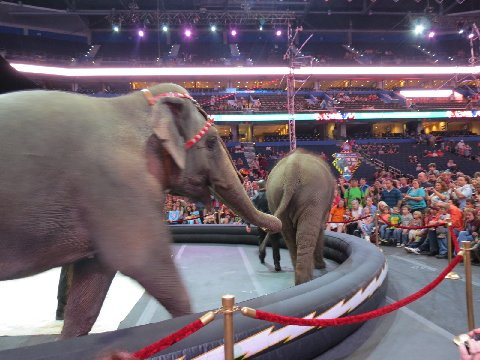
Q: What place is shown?
A: It is a stadium.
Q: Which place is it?
A: It is a stadium.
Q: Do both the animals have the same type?
A: Yes, all the animals are elephants.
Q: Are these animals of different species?
A: No, all the animals are elephants.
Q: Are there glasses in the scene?
A: No, there are no glasses.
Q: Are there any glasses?
A: No, there are no glasses.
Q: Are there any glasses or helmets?
A: No, there are no glasses or helmets.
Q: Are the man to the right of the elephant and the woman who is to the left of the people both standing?
A: Yes, both the man and the woman are standing.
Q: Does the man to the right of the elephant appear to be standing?
A: Yes, the man is standing.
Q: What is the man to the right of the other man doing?
A: The man is standing.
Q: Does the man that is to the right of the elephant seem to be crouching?
A: No, the man is standing.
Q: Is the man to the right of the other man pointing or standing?
A: The man is standing.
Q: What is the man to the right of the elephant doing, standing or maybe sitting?
A: The man is standing.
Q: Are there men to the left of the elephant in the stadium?
A: No, the man is to the right of the elephant.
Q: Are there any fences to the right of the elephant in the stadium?
A: No, there is a man to the right of the elephant.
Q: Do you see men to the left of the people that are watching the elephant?
A: Yes, there is a man to the left of the people.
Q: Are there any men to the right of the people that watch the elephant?
A: No, the man is to the left of the people.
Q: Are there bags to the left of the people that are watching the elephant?
A: No, there is a man to the left of the people.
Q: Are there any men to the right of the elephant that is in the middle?
A: Yes, there is a man to the right of the elephant.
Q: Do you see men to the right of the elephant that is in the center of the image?
A: Yes, there is a man to the right of the elephant.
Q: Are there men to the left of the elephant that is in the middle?
A: No, the man is to the right of the elephant.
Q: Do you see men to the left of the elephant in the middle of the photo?
A: No, the man is to the right of the elephant.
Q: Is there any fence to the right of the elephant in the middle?
A: No, there is a man to the right of the elephant.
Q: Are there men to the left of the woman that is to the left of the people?
A: Yes, there is a man to the left of the woman.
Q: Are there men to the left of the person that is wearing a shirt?
A: Yes, there is a man to the left of the woman.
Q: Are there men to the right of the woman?
A: No, the man is to the left of the woman.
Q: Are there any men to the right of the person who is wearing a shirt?
A: No, the man is to the left of the woman.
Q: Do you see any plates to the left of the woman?
A: No, there is a man to the left of the woman.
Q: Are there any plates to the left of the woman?
A: No, there is a man to the left of the woman.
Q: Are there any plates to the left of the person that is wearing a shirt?
A: No, there is a man to the left of the woman.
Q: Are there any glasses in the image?
A: No, there are no glasses.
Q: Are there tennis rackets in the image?
A: No, there are no tennis rackets.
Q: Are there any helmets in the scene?
A: No, there are no helmets.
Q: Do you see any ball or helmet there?
A: No, there are no helmets or balls.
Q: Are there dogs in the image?
A: No, there are no dogs.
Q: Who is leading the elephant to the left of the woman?
A: The man is leading the elephant.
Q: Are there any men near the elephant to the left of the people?
A: Yes, there is a man near the elephant.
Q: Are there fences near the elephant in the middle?
A: No, there is a man near the elephant.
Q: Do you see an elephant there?
A: Yes, there is an elephant.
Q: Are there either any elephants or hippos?
A: Yes, there is an elephant.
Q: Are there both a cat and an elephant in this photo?
A: No, there is an elephant but no cats.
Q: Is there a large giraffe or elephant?
A: Yes, there is a large elephant.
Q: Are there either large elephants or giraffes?
A: Yes, there is a large elephant.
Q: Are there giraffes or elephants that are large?
A: Yes, the elephant is large.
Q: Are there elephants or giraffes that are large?
A: Yes, the elephant is large.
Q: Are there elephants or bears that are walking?
A: Yes, the elephant is walking.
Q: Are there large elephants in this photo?
A: Yes, there is a large elephant.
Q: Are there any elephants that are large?
A: Yes, there is an elephant that is large.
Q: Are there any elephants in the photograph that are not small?
A: Yes, there is a large elephant.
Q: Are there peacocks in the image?
A: No, there are no peacocks.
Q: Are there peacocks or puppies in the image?
A: No, there are no peacocks or puppies.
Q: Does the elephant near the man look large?
A: Yes, the elephant is large.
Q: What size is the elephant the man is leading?
A: The elephant is large.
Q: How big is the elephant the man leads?
A: The elephant is large.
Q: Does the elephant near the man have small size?
A: No, the elephant is large.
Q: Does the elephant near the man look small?
A: No, the elephant is large.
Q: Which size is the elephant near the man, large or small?
A: The elephant is large.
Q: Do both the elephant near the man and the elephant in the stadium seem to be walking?
A: Yes, both the elephant and the elephant are walking.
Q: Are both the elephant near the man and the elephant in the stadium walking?
A: Yes, both the elephant and the elephant are walking.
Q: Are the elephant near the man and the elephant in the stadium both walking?
A: Yes, both the elephant and the elephant are walking.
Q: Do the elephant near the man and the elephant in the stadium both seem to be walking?
A: Yes, both the elephant and the elephant are walking.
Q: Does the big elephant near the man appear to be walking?
A: Yes, the elephant is walking.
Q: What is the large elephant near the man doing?
A: The elephant is walking.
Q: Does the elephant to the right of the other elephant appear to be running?
A: No, the elephant is walking.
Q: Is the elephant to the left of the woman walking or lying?
A: The elephant is walking.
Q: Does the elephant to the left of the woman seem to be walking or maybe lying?
A: The elephant is walking.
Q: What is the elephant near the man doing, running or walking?
A: The elephant is walking.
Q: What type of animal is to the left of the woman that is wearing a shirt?
A: The animal is an elephant.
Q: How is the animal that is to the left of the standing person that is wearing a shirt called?
A: The animal is an elephant.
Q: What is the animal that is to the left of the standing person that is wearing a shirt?
A: The animal is an elephant.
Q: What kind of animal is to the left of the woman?
A: The animal is an elephant.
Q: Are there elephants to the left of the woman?
A: Yes, there is an elephant to the left of the woman.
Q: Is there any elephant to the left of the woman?
A: Yes, there is an elephant to the left of the woman.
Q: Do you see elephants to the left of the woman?
A: Yes, there is an elephant to the left of the woman.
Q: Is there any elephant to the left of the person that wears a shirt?
A: Yes, there is an elephant to the left of the woman.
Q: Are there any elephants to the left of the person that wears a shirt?
A: Yes, there is an elephant to the left of the woman.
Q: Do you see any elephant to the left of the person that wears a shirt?
A: Yes, there is an elephant to the left of the woman.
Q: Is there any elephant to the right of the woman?
A: No, the elephant is to the left of the woman.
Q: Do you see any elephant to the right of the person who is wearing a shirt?
A: No, the elephant is to the left of the woman.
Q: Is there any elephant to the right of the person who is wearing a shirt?
A: No, the elephant is to the left of the woman.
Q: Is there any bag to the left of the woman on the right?
A: No, there is an elephant to the left of the woman.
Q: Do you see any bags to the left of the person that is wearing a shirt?
A: No, there is an elephant to the left of the woman.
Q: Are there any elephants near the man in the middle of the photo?
A: Yes, there is an elephant near the man.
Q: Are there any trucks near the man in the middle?
A: No, there is an elephant near the man.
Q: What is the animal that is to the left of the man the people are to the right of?
A: The animal is an elephant.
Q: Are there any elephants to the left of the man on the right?
A: Yes, there is an elephant to the left of the man.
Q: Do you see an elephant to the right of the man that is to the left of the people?
A: No, the elephant is to the left of the man.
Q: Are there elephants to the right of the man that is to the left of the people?
A: No, the elephant is to the left of the man.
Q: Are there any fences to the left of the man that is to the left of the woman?
A: No, there is an elephant to the left of the man.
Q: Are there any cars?
A: No, there are no cars.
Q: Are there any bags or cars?
A: No, there are no cars or bags.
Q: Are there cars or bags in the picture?
A: No, there are no cars or bags.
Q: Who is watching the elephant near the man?
A: The people are watching the elephant.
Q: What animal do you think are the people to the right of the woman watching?
A: The people are watching the elephant.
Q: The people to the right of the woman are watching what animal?
A: The people are watching the elephant.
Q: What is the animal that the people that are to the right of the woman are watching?
A: The animal is an elephant.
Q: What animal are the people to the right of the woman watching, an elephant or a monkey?
A: The people are watching an elephant.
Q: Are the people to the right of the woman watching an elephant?
A: Yes, the people are watching an elephant.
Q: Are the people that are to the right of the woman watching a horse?
A: No, the people are watching an elephant.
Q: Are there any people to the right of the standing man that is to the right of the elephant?
A: Yes, there are people to the right of the man.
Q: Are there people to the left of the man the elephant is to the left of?
A: No, the people are to the right of the man.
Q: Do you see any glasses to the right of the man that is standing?
A: No, there are people to the right of the man.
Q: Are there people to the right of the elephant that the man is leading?
A: Yes, there are people to the right of the elephant.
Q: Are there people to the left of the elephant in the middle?
A: No, the people are to the right of the elephant.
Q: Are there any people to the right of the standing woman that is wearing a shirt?
A: Yes, there are people to the right of the woman.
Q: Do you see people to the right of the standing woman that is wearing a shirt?
A: Yes, there are people to the right of the woman.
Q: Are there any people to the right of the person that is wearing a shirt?
A: Yes, there are people to the right of the woman.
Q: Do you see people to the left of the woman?
A: No, the people are to the right of the woman.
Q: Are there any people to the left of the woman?
A: No, the people are to the right of the woman.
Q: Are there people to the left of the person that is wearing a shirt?
A: No, the people are to the right of the woman.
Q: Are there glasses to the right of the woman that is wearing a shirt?
A: No, there are people to the right of the woman.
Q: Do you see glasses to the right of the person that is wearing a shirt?
A: No, there are people to the right of the woman.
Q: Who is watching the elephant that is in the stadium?
A: The people are watching the elephant.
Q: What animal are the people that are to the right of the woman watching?
A: The people are watching the elephant.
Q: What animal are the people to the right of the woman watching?
A: The people are watching the elephant.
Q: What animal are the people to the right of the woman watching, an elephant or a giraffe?
A: The people are watching an elephant.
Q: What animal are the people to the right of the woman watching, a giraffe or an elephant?
A: The people are watching an elephant.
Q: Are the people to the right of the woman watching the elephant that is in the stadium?
A: Yes, the people are watching the elephant.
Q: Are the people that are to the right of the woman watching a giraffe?
A: No, the people are watching the elephant.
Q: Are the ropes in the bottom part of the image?
A: Yes, the ropes are in the bottom of the image.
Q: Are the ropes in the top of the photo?
A: No, the ropes are in the bottom of the image.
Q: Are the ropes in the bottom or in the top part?
A: The ropes are in the bottom of the image.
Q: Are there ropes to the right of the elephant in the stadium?
A: Yes, there are ropes to the right of the elephant.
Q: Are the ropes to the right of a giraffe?
A: No, the ropes are to the right of the elephant.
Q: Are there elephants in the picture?
A: Yes, there is an elephant.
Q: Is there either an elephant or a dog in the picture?
A: Yes, there is an elephant.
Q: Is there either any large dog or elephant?
A: Yes, there is a large elephant.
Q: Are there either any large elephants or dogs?
A: Yes, there is a large elephant.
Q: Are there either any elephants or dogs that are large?
A: Yes, the elephant is large.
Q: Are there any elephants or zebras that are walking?
A: Yes, the elephant is walking.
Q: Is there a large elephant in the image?
A: Yes, there is a large elephant.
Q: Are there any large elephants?
A: Yes, there is a large elephant.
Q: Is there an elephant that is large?
A: Yes, there is an elephant that is large.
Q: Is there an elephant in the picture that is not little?
A: Yes, there is a large elephant.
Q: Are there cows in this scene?
A: No, there are no cows.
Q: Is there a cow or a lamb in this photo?
A: No, there are no cows or lambs.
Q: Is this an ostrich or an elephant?
A: This is an elephant.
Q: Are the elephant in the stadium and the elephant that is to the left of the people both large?
A: Yes, both the elephant and the elephant are large.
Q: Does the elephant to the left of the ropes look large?
A: Yes, the elephant is large.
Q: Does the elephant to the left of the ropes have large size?
A: Yes, the elephant is large.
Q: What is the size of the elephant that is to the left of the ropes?
A: The elephant is large.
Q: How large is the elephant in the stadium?
A: The elephant is large.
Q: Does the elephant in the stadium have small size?
A: No, the elephant is large.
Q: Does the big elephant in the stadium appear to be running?
A: No, the elephant is walking.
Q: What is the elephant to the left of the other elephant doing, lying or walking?
A: The elephant is walking.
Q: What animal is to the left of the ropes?
A: The animal is an elephant.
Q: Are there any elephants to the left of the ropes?
A: Yes, there is an elephant to the left of the ropes.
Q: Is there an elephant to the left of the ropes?
A: Yes, there is an elephant to the left of the ropes.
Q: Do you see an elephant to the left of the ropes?
A: Yes, there is an elephant to the left of the ropes.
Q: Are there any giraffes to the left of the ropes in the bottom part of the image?
A: No, there is an elephant to the left of the ropes.